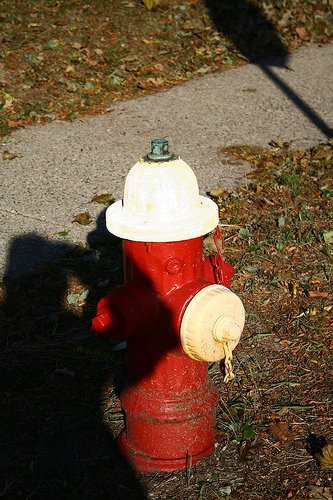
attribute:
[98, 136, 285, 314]
hydrant — white, red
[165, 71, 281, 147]
debris — red, brown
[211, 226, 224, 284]
chain — red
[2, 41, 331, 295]
sidewalk — spotted, grey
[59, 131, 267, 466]
hydrant — red, white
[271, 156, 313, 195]
grass — green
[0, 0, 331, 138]
leaves — green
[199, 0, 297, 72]
sign — stop sign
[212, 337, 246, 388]
chain — white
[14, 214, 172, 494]
shadow — person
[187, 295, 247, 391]
chain hydrant — white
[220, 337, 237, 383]
chain — white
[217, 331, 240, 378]
chain — white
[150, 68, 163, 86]
leaf — brown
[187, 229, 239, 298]
chain — red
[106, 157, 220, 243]
top — white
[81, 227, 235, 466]
bottom — red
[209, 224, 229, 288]
chain — red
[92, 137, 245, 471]
hydrant — white, fire hydrant, red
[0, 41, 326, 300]
path — gray, gravel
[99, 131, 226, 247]
cap — white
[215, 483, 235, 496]
rock — small